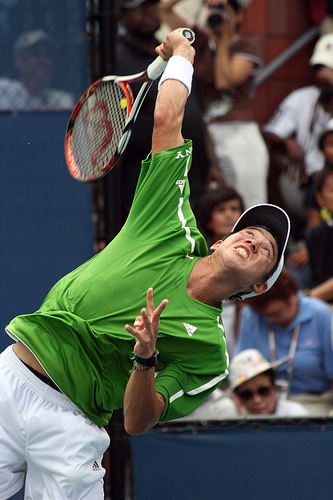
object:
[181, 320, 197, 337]
logo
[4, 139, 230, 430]
shirt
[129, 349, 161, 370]
watch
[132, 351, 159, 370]
wrist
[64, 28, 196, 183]
raquet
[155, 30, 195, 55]
hand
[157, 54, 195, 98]
armband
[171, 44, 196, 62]
wrist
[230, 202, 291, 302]
hat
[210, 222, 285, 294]
head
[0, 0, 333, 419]
spectators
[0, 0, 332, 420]
stands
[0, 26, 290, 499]
player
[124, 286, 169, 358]
hand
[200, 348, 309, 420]
woman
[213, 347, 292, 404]
hat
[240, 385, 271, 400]
sunglasses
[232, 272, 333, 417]
person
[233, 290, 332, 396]
blue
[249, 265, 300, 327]
head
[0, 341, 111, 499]
shorts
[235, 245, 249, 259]
teeth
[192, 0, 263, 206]
woman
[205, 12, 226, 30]
camera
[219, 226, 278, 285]
face